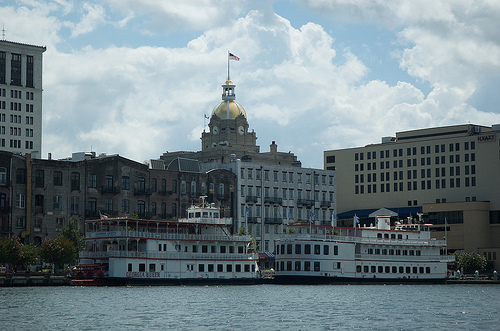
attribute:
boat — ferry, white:
[93, 220, 281, 282]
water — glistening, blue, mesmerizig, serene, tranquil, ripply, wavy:
[0, 277, 497, 330]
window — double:
[351, 150, 371, 163]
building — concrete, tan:
[327, 139, 495, 264]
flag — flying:
[213, 43, 250, 79]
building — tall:
[190, 75, 272, 161]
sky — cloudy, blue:
[26, 9, 498, 138]